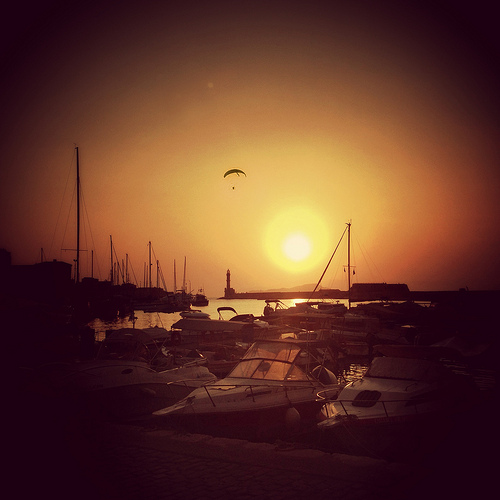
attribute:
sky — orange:
[254, 113, 498, 218]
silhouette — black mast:
[314, 213, 371, 315]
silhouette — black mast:
[114, 251, 134, 293]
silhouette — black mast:
[112, 260, 121, 289]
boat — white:
[316, 337, 454, 431]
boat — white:
[150, 307, 351, 425]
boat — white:
[66, 338, 225, 407]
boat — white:
[178, 297, 264, 347]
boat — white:
[330, 305, 384, 361]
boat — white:
[316, 338, 452, 439]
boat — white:
[174, 301, 264, 356]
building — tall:
[223, 267, 235, 299]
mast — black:
[104, 233, 119, 288]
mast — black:
[178, 258, 192, 301]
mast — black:
[75, 242, 99, 294]